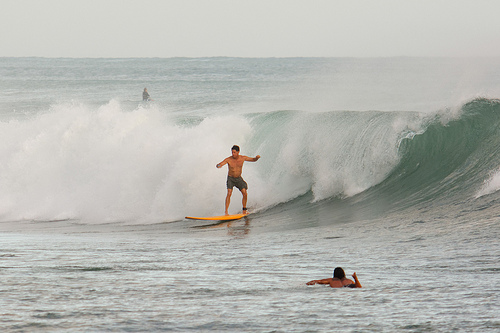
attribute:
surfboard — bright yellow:
[183, 209, 245, 224]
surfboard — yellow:
[186, 207, 253, 222]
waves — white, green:
[4, 100, 404, 221]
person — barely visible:
[220, 151, 272, 211]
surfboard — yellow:
[183, 213, 248, 219]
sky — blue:
[219, 23, 276, 45]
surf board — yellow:
[183, 206, 251, 223]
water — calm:
[18, 227, 493, 331]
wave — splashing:
[1, 90, 497, 232]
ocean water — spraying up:
[264, 70, 445, 236]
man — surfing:
[213, 138, 263, 221]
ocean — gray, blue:
[0, 54, 497, 331]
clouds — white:
[387, 15, 424, 69]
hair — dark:
[332, 267, 344, 278]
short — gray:
[222, 174, 250, 193]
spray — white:
[32, 94, 216, 176]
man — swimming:
[268, 243, 376, 305]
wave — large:
[351, 103, 466, 199]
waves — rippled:
[306, 103, 496, 205]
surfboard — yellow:
[183, 204, 268, 231]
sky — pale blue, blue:
[0, 0, 499, 58]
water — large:
[102, 99, 479, 234]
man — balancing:
[218, 146, 255, 217]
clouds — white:
[40, 8, 452, 53]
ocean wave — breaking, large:
[0, 102, 495, 223]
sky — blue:
[40, 22, 174, 63]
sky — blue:
[6, 14, 497, 53]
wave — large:
[240, 96, 498, 233]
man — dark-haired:
[216, 132, 266, 204]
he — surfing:
[216, 143, 263, 217]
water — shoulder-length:
[222, 248, 434, 323]